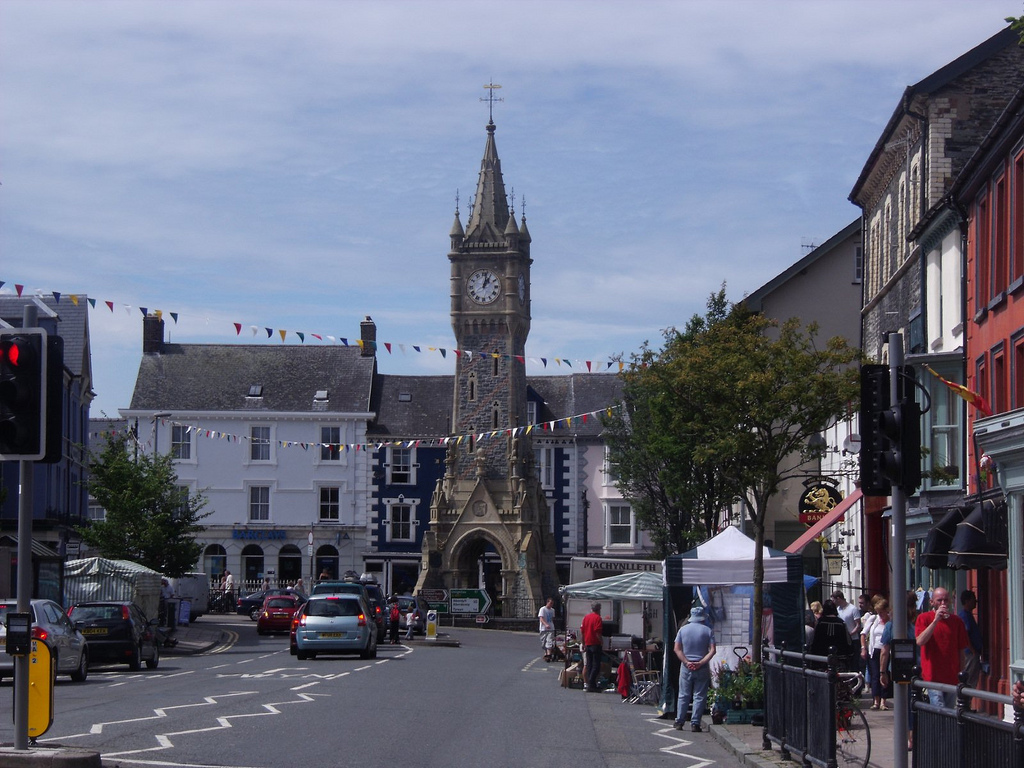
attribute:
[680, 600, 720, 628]
hat — blue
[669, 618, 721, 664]
shirt — blue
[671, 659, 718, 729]
pants — blue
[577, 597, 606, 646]
shirt — red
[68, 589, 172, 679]
station wagon — dark blue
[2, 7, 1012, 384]
sky — blue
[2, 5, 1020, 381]
clouds — wispy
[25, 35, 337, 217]
cloud — big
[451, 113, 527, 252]
roof — pointy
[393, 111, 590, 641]
tower — brown, clock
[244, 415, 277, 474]
window — rectangular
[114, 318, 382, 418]
roof — brown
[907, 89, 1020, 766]
building — red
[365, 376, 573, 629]
building — white, blue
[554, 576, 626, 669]
shirt — red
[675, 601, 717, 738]
man — standing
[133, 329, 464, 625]
building — tall, white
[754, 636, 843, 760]
railing — black, metal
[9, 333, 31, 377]
signal — traffic, light, red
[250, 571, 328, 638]
red car — red 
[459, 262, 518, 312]
white clock — white 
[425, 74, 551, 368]
grey tower — grey  